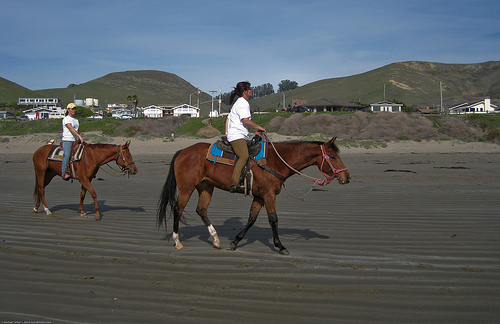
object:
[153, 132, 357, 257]
horse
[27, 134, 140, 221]
horse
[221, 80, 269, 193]
woman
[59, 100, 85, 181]
woman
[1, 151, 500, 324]
beach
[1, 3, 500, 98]
sky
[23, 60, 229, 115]
hill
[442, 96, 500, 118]
house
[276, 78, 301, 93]
tree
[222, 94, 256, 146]
shirt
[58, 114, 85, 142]
shirt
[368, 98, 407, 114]
house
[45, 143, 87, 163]
blanket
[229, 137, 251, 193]
pants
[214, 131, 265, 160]
saddle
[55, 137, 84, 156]
saddle